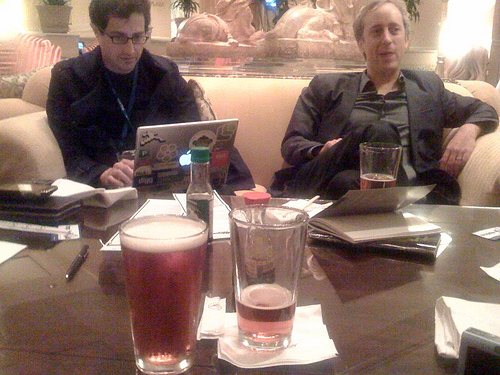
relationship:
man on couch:
[46, 0, 257, 196] [0, 64, 500, 208]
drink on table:
[358, 137, 401, 191] [0, 207, 499, 371]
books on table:
[307, 183, 445, 262] [0, 207, 499, 371]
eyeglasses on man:
[99, 30, 148, 44] [49, 0, 203, 125]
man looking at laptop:
[49, 0, 203, 125] [129, 116, 238, 190]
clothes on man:
[269, 64, 499, 201] [273, 1, 498, 210]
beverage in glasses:
[124, 243, 201, 358] [92, 200, 309, 374]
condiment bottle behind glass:
[186, 145, 213, 242] [229, 203, 310, 351]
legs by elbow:
[287, 120, 407, 194] [457, 95, 497, 122]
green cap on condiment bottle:
[188, 145, 210, 165] [186, 147, 213, 245]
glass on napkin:
[229, 203, 310, 351] [216, 302, 337, 369]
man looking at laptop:
[46, 0, 257, 196] [129, 116, 238, 190]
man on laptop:
[46, 0, 257, 196] [132, 119, 239, 195]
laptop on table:
[132, 119, 239, 195] [119, 208, 386, 301]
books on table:
[307, 183, 445, 262] [2, 179, 497, 374]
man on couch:
[46, 0, 257, 196] [3, 60, 497, 202]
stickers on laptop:
[138, 123, 235, 190] [116, 118, 238, 190]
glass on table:
[223, 198, 317, 364] [1, 156, 498, 373]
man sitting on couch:
[273, 1, 498, 210] [3, 60, 497, 202]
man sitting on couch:
[46, 0, 257, 196] [195, 75, 281, 183]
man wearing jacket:
[273, 1, 498, 210] [267, 67, 497, 201]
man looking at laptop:
[46, 0, 257, 196] [126, 110, 238, 187]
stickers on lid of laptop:
[137, 130, 228, 185] [124, 118, 264, 188]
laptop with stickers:
[124, 118, 264, 188] [137, 130, 228, 185]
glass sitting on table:
[356, 141, 406, 212] [2, 179, 497, 374]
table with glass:
[2, 179, 497, 374] [356, 141, 406, 212]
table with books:
[2, 179, 497, 374] [311, 187, 441, 268]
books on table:
[311, 187, 441, 268] [2, 179, 497, 374]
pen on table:
[62, 240, 91, 282] [0, 193, 500, 375]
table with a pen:
[0, 193, 500, 375] [62, 240, 91, 282]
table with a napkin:
[2, 179, 497, 374] [219, 309, 338, 370]